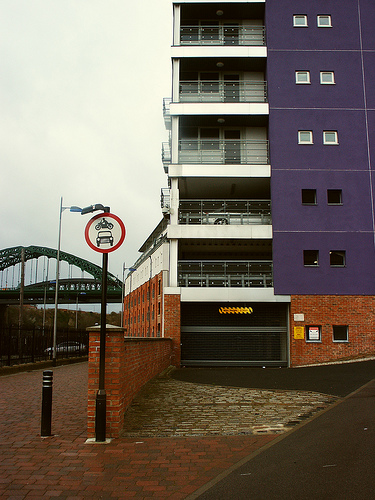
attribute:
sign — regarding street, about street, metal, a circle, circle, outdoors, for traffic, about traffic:
[85, 214, 126, 253]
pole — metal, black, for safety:
[96, 252, 109, 443]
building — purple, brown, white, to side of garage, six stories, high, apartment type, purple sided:
[123, 5, 372, 363]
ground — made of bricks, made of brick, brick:
[4, 362, 284, 494]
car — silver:
[47, 342, 87, 359]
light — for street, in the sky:
[51, 196, 82, 363]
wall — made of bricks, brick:
[85, 327, 174, 444]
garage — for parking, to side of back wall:
[2, 325, 87, 373]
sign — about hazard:
[218, 306, 254, 315]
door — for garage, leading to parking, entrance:
[180, 331, 289, 363]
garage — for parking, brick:
[176, 177, 292, 367]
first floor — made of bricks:
[163, 288, 373, 369]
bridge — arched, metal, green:
[2, 246, 123, 304]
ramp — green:
[180, 365, 372, 495]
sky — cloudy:
[6, 6, 172, 316]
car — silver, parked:
[198, 207, 271, 224]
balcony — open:
[161, 98, 173, 130]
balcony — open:
[162, 142, 172, 163]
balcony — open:
[160, 186, 170, 215]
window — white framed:
[293, 16, 309, 28]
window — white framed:
[318, 14, 331, 29]